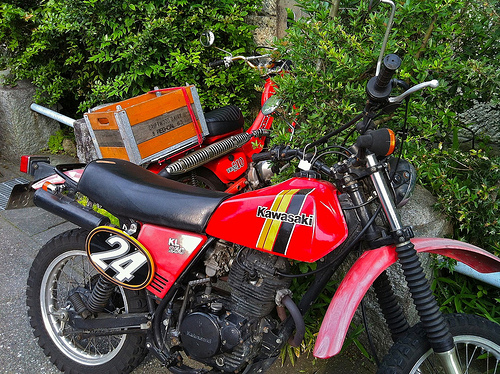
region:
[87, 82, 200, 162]
An orange box on a motorcycle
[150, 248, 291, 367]
An engine on a motorcycle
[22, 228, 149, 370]
The back tire on a motorcycle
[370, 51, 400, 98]
A grip on a handlebar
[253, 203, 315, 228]
a logo on a motorcycle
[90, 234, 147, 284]
a 24 on a motorcycle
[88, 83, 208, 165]
a wooden box on the back of a bike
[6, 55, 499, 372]
a red and black motorcycle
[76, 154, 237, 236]
a black leather bike seat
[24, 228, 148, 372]
a motorcycles black wheel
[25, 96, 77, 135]
a pole between two rocks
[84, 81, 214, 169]
a box on the back of a bike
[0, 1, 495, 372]
a motorcycle leaned against a bush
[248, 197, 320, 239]
a logo for a motorcycle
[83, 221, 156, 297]
a number sign on a bike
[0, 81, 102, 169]
two rocks with poles between them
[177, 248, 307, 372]
an engine on a bike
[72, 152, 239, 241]
a leather bike seat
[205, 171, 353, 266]
A fuel tank on a motorcycle.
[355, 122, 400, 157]
A right blinker on a bike.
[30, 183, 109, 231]
An exhaust pipe on a motorcycle.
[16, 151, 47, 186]
A tail light on a motorcycle.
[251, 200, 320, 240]
A name written on a motorcycle.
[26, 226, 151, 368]
A rear tire on a motorcycle.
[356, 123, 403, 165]
A blinker on a bike.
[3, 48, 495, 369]
red motorcycle parked next to bushes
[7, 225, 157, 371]
back wheel on motorcycle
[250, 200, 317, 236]
brand name on side of motorcycle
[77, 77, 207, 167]
orange wooden crate on back of motorcycle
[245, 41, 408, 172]
black handlebars on motorcycle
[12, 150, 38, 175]
red light on back of motorcycle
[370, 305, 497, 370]
front wheel of motorcycle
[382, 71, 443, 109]
metal level next to handlebars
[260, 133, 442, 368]
a bike parked on street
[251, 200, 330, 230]
word on a motorcycle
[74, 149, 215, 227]
seat of a motorcycle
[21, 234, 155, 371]
back tire of a bike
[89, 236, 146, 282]
the number 24 on a bike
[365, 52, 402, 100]
a black rubber handle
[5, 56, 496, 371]
a red kawasaki motorcycle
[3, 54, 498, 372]
a red motorcycle with a black seat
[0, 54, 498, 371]
a motorcycle with the number 24 on it's side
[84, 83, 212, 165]
an orange colored crate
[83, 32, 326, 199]
a red scooter with a crate on the back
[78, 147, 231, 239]
a black motorcycle seat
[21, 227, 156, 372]
black wheel on a motorcycle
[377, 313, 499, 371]
black wheel on a motorcycle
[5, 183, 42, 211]
license plate on a motorcycle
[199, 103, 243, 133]
black seat on a scooter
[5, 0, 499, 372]
motorcycle is red and black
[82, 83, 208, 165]
wooden crate is orange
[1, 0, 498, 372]
black seat on motorcycle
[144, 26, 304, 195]
motorcycle is red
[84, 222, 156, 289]
white number on black logo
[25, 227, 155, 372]
tire is round with chrome rims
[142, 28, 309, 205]
side mirror on red motorcycle